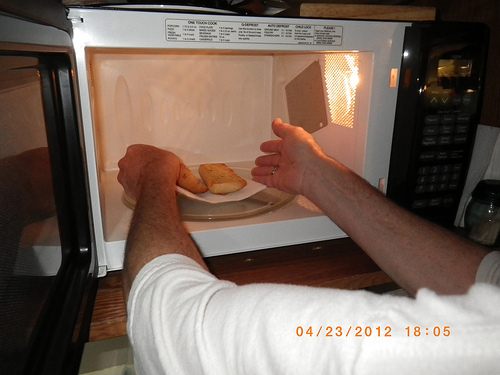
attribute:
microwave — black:
[25, 32, 491, 269]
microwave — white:
[1, 7, 412, 374]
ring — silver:
[266, 161, 281, 178]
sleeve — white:
[118, 253, 498, 373]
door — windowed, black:
[0, 16, 105, 365]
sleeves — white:
[124, 251, 499, 371]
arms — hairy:
[115, 116, 492, 293]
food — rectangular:
[178, 161, 250, 198]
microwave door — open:
[0, 15, 97, 374]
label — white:
[168, 15, 346, 49]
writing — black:
[158, 15, 349, 50]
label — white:
[162, 16, 347, 47]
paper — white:
[174, 154, 271, 204]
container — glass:
[464, 179, 499, 243]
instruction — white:
[160, 15, 347, 50]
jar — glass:
[465, 176, 497, 245]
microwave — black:
[33, 3, 483, 229]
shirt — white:
[150, 245, 418, 372]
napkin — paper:
[175, 175, 268, 205]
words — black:
[165, 18, 343, 48]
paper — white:
[172, 175, 269, 203]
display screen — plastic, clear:
[434, 48, 484, 80]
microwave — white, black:
[1, 12, 488, 373]